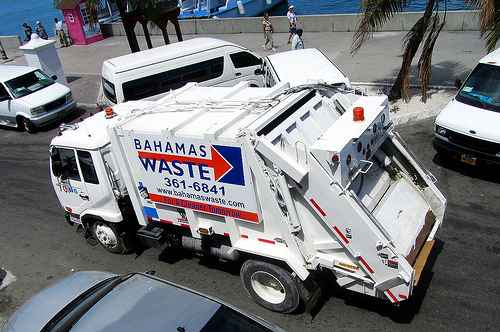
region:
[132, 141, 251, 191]
a version of the red arrow fedex logo, sort of, but this time involving island garbage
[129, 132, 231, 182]
'bahamas ?? waste' [more or less]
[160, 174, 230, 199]
'361-6841' [an area small enough not to need an area code]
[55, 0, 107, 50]
pink kiosk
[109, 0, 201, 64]
the silhouettes of three palm trees beside the silhouette of a power pole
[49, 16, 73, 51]
man in white shirt, khaki pants leans on pink kiosk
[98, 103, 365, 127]
two bright orange 'warning lights' atop bahamian garbage truck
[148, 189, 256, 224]
'.....for a cleaner tomorrow.....'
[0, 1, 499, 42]
water is placid, sapphire, deep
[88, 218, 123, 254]
a heavy white hubcap, multi-lugnuts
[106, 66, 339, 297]
a white garbage truck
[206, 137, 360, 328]
a white garbage truck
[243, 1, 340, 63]
People walking on the sidewalk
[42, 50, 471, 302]
Large white garbage truck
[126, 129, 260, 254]
Red and blue sign on side of truck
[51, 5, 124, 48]
Pink building with straw roof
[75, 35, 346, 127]
White vans parked on side of street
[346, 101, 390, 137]
Orange light on top of the truck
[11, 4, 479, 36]
Water next to the sidewalk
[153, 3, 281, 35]
Blue boat by the cement wall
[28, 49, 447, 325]
Truck is in the middle of the street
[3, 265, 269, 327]
The car is silver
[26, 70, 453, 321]
A waste management truck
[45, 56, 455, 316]
Waste management is white in color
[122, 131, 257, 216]
Company Label is on the side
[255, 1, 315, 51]
People in the background walking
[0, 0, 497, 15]
A body of water is in the background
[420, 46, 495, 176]
A white van in the foreground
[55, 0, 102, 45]
A small pink house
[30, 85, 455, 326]
Waste management truck is on the road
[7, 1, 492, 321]
Photo was taken in the daytime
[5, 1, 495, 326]
Photo was taken outside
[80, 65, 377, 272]
a large white garbage truck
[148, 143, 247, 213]
red white and blue sign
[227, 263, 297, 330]
black tire with white rim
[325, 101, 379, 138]
a smallorange light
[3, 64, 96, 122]
white van parked on road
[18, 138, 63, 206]
side mirror of a vehicle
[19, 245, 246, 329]
gray vehicle parkedon road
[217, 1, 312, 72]
three people walkin near water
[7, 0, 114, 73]
little pink house by water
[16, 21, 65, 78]
a white pillar near sude walk